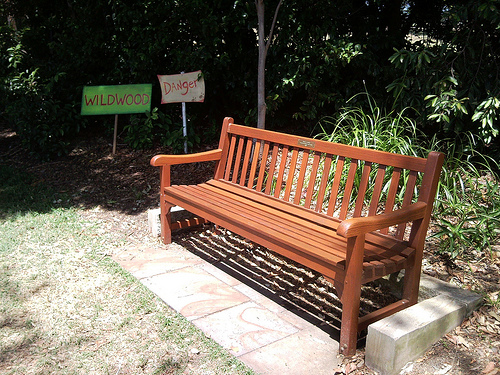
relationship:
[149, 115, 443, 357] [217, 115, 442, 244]
bench has a back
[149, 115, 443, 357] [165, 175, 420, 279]
bench has a bottom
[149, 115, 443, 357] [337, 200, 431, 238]
bench has an arm rest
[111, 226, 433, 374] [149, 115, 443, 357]
concrete under bench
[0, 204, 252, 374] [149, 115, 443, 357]
grass in front of bench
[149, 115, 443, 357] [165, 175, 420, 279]
bench has a seat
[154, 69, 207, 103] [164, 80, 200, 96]
sign says danger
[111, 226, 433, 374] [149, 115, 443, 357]
tile under bench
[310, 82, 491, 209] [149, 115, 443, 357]
plant behind bench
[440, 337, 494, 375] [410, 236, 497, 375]
shadow on ground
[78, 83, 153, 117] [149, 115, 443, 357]
board by bench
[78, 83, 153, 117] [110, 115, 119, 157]
board on a pole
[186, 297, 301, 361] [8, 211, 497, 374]
block on ground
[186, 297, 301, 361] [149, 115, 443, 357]
block under bench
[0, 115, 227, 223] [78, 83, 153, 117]
shadow over sign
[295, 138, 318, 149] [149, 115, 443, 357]
plaque on bench